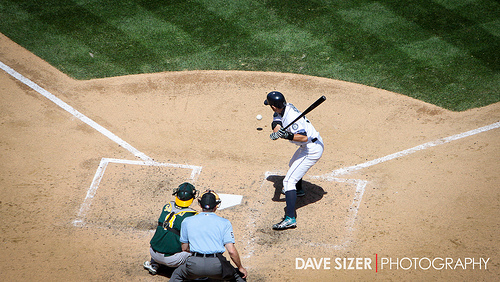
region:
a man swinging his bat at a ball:
[251, 77, 331, 241]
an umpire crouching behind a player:
[166, 189, 246, 278]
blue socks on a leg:
[272, 191, 304, 218]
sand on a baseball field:
[149, 89, 228, 148]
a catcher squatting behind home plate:
[145, 180, 188, 271]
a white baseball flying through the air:
[241, 106, 270, 125]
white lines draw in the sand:
[18, 94, 138, 141]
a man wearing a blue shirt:
[173, 194, 245, 277]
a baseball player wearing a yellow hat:
[171, 182, 193, 210]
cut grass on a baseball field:
[264, 22, 356, 60]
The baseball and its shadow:
[248, 109, 265, 134]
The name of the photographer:
[290, 251, 373, 277]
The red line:
[372, 251, 379, 274]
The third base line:
[0, 57, 160, 164]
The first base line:
[317, 110, 499, 175]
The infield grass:
[0, 0, 497, 113]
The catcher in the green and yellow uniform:
[142, 178, 199, 273]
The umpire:
[169, 190, 261, 280]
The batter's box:
[232, 161, 377, 258]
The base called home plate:
[200, 186, 245, 209]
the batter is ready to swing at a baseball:
[255, 88, 326, 229]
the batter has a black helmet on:
[263, 89, 288, 111]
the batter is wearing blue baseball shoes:
[273, 188, 310, 231]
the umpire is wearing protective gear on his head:
[174, 191, 246, 280]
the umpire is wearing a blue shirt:
[178, 190, 237, 252]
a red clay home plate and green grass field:
[5, 25, 496, 276]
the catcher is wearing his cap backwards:
[141, 180, 198, 278]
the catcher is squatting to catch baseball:
[141, 182, 195, 274]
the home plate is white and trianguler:
[204, 185, 245, 215]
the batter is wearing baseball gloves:
[268, 125, 295, 144]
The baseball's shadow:
[252, 121, 266, 136]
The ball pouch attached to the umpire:
[217, 251, 239, 281]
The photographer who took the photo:
[292, 254, 374, 280]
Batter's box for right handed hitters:
[68, 151, 205, 251]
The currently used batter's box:
[237, 164, 374, 266]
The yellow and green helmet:
[172, 180, 197, 209]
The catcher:
[142, 181, 197, 273]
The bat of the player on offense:
[271, 92, 330, 133]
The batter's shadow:
[262, 171, 327, 214]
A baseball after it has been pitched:
[247, 110, 269, 125]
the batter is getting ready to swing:
[263, 88, 335, 233]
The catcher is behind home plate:
[141, 174, 193, 276]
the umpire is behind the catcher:
[175, 184, 242, 279]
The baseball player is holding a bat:
[255, 77, 352, 229]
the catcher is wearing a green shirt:
[150, 200, 196, 257]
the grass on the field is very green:
[2, 1, 498, 117]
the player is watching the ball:
[245, 81, 370, 251]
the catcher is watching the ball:
[142, 174, 194, 271]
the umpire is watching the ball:
[168, 185, 257, 280]